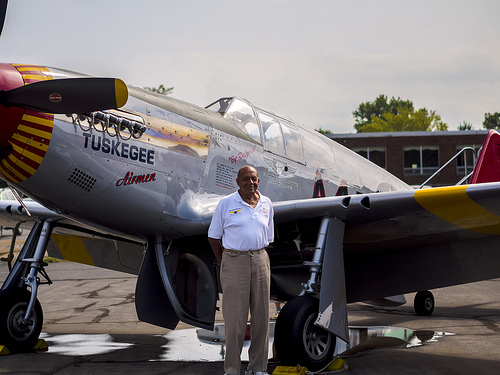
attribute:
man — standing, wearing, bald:
[226, 167, 280, 370]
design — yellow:
[219, 203, 264, 223]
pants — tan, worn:
[217, 243, 302, 324]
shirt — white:
[212, 202, 312, 262]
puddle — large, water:
[69, 330, 216, 374]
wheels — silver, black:
[293, 311, 340, 374]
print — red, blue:
[104, 154, 180, 225]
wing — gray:
[346, 193, 499, 252]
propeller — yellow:
[69, 73, 196, 142]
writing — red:
[96, 171, 182, 193]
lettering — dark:
[76, 132, 180, 167]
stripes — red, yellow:
[12, 115, 68, 183]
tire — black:
[281, 307, 348, 364]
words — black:
[62, 131, 212, 161]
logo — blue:
[224, 205, 246, 221]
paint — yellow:
[423, 177, 451, 200]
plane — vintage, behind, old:
[26, 47, 442, 237]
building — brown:
[367, 122, 492, 180]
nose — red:
[1, 61, 37, 93]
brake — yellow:
[277, 353, 367, 362]